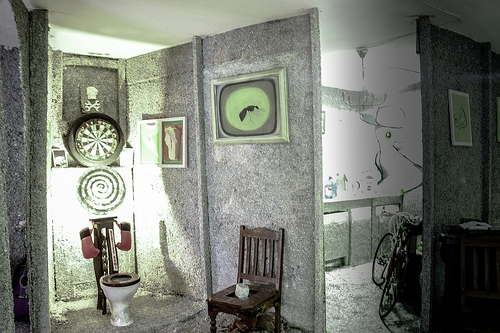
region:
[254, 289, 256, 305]
the chair is wooden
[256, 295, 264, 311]
the chair is wooden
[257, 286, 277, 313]
the chair is wooden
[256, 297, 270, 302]
the chair is wooden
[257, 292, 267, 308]
the chair is wooden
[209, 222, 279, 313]
the chair is old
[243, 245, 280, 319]
the chair is old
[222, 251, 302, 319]
the chair is old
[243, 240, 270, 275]
the chair is old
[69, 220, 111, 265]
the gloves is red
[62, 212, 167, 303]
the gloves is red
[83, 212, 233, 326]
the gloves is red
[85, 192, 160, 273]
the gloves is red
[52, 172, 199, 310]
the gloves is red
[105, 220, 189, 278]
the gloves is red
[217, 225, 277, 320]
this is a chair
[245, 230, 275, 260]
the chair is wooden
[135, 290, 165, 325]
this is the floor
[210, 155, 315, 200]
the wall looks old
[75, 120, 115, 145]
this is a clock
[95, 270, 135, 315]
this is a toilet sink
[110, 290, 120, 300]
the sink is white in color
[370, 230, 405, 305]
this is a bicycle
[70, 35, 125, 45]
this is the roof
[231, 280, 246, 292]
this is a stone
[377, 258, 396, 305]
the bike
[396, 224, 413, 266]
the bike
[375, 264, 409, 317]
the bike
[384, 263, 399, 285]
the bike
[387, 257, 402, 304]
the bike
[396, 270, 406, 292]
the bike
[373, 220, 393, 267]
the bike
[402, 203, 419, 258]
the bike